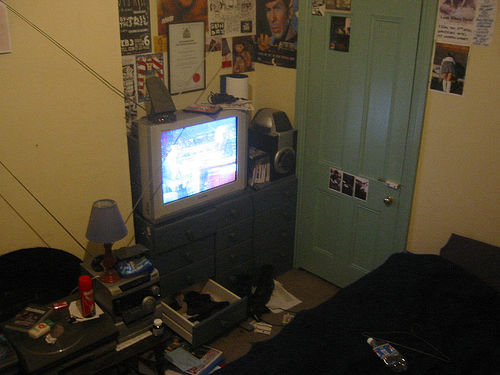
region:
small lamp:
[91, 190, 162, 261]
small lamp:
[34, 164, 176, 272]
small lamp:
[68, 207, 130, 259]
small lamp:
[54, 197, 148, 274]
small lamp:
[74, 194, 185, 315]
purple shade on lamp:
[83, 189, 130, 278]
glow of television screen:
[152, 102, 248, 213]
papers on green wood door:
[316, 159, 371, 217]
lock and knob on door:
[368, 168, 401, 216]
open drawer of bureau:
[166, 272, 261, 345]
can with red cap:
[68, 268, 105, 330]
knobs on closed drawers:
[215, 192, 247, 279]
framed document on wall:
[164, 12, 212, 101]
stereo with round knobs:
[106, 269, 168, 343]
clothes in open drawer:
[175, 284, 225, 326]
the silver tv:
[136, 107, 247, 213]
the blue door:
[294, 3, 411, 283]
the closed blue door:
[295, 5, 435, 281]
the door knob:
[382, 194, 393, 207]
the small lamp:
[88, 200, 128, 285]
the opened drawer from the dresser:
[160, 281, 246, 342]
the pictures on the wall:
[118, 0, 298, 93]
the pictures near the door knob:
[322, 165, 368, 200]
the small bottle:
[150, 316, 165, 334]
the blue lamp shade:
[86, 199, 128, 244]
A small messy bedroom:
[25, 50, 432, 326]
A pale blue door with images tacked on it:
[302, 7, 388, 272]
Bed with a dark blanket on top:
[360, 245, 490, 372]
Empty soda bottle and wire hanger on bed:
[356, 310, 446, 371]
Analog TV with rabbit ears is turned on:
[130, 45, 261, 206]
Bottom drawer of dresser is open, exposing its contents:
[161, 263, 272, 318]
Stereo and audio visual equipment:
[23, 232, 176, 347]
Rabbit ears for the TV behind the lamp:
[12, 111, 147, 267]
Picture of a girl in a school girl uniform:
[417, 30, 475, 101]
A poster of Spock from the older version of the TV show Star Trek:
[251, 0, 303, 76]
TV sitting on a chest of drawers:
[140, 95, 262, 223]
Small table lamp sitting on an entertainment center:
[77, 189, 122, 281]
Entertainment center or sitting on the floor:
[82, 261, 167, 365]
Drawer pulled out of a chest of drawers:
[158, 269, 254, 351]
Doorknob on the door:
[378, 189, 395, 211]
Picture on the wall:
[427, 38, 475, 99]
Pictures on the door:
[324, 161, 371, 205]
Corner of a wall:
[108, 11, 133, 188]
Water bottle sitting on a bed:
[360, 323, 412, 373]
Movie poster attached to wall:
[245, 0, 295, 69]